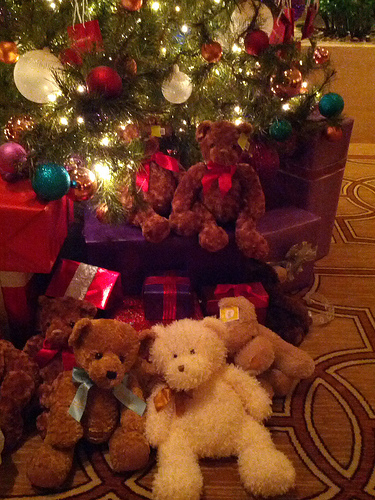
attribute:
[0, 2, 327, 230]
christmas tree — decorated, lit up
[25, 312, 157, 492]
bear — dark brown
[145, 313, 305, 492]
teddy bear — fuzzy, white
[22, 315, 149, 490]
teddy bear — brown, soft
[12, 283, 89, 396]
teddy bear — soft, brown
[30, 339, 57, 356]
ribbon — red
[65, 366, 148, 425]
ribbon — blue, LIGHT BLUE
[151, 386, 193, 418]
ribbon — BROWN, SATIN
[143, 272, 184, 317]
ribbon — RED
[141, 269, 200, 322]
present — PURPLE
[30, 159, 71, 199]
ornament — SPARKLY, TEAL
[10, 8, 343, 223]
tree — CHRISTMAS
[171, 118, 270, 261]
bear — TEDDY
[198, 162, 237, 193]
ribbon — RED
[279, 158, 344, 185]
ribbon — PURPLE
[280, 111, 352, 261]
present — PURPLE, TALL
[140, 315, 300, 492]
bear — LIGHT BROWN, WHITE, TEDDY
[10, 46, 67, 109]
ornament — LARGE, WHITE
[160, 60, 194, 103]
ornament — SMALL, GLASS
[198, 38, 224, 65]
ornament — SMALL, RED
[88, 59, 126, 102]
ornament — red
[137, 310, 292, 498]
teddy bear — white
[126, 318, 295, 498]
teddy bear — white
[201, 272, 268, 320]
gift box — red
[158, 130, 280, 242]
bear — brown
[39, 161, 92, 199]
ornament — blue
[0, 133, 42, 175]
ornament — purple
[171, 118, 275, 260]
teddy bear — brown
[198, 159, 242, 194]
ribbon — red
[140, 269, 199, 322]
box — purple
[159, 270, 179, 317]
lace — pink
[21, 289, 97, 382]
teddy bear — brown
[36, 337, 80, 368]
ribbon — red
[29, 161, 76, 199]
ornament — green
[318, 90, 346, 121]
ornament — green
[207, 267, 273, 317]
box — pink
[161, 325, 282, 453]
teddy bear — white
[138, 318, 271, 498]
teddy bear — white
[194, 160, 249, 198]
bow — red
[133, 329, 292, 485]
teddy bear — white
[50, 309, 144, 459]
teddy bear — brown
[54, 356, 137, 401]
ribbon — blue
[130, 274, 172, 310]
wrapping — purple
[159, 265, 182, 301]
ribbon — red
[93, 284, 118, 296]
paper — wrapping , red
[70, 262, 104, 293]
trim — silver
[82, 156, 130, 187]
christmas tree — white lights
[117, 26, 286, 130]
tree — ornaments 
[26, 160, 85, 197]
table — green ornament  